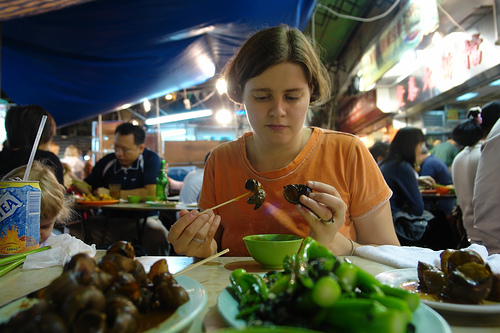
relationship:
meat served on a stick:
[246, 178, 267, 211] [203, 188, 252, 216]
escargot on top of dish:
[112, 296, 139, 331] [1, 270, 210, 332]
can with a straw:
[0, 175, 43, 258] [23, 110, 51, 180]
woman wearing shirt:
[165, 24, 404, 260] [195, 126, 394, 261]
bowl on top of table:
[243, 232, 305, 271] [1, 247, 499, 332]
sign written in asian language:
[375, 17, 499, 116] [395, 31, 485, 105]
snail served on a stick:
[149, 254, 175, 283] [175, 246, 230, 282]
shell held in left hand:
[281, 183, 314, 208] [293, 179, 349, 258]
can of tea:
[0, 175, 43, 258] [2, 196, 20, 223]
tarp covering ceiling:
[0, 0, 318, 135] [0, 0, 379, 133]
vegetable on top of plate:
[304, 306, 408, 332] [215, 269, 452, 331]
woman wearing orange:
[165, 24, 404, 260] [195, 126, 394, 261]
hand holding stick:
[164, 207, 223, 260] [203, 188, 252, 216]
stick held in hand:
[203, 188, 252, 216] [164, 207, 223, 260]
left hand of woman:
[293, 179, 349, 258] [165, 24, 404, 260]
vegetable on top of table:
[314, 274, 343, 308] [1, 247, 499, 332]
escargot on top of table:
[112, 296, 139, 331] [1, 247, 499, 332]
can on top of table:
[0, 175, 43, 258] [1, 247, 499, 332]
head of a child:
[2, 162, 65, 246] [1, 162, 93, 248]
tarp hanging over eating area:
[0, 0, 318, 135] [0, 98, 499, 331]